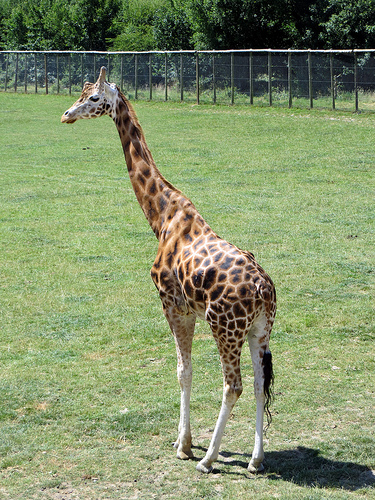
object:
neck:
[116, 110, 183, 232]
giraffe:
[58, 66, 278, 475]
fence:
[0, 51, 374, 111]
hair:
[260, 352, 274, 438]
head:
[57, 67, 125, 126]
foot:
[176, 434, 194, 461]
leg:
[206, 332, 240, 456]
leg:
[247, 348, 276, 457]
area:
[0, 61, 370, 499]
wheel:
[8, 80, 31, 92]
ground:
[1, 89, 367, 497]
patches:
[190, 262, 240, 299]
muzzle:
[61, 102, 99, 123]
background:
[2, 0, 374, 107]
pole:
[264, 52, 274, 103]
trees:
[2, 0, 374, 88]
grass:
[1, 87, 372, 498]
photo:
[0, 3, 373, 500]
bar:
[7, 50, 374, 56]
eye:
[89, 95, 101, 104]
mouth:
[62, 115, 74, 126]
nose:
[64, 109, 69, 118]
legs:
[169, 312, 193, 439]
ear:
[104, 81, 116, 101]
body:
[148, 218, 273, 343]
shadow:
[264, 444, 374, 494]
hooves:
[200, 455, 215, 471]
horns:
[96, 65, 111, 83]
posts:
[196, 55, 307, 103]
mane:
[122, 93, 177, 196]